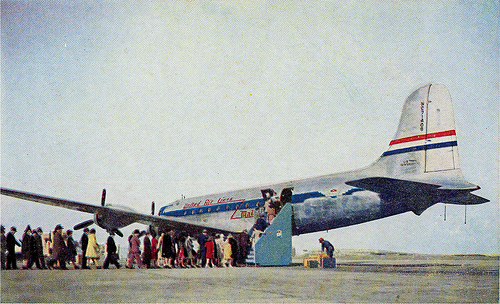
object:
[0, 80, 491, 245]
plane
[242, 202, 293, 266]
stair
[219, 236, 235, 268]
person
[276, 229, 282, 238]
sign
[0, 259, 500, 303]
ground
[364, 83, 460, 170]
tail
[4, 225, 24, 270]
people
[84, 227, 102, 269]
girl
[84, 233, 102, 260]
coat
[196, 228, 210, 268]
man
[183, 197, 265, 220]
text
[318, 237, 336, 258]
man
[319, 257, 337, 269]
luggage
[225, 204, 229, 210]
window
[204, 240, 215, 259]
coat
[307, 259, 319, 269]
bag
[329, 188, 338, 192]
red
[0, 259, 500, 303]
tarmac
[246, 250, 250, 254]
step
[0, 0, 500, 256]
sky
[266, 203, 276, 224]
passeners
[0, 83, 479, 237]
port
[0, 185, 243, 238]
wing